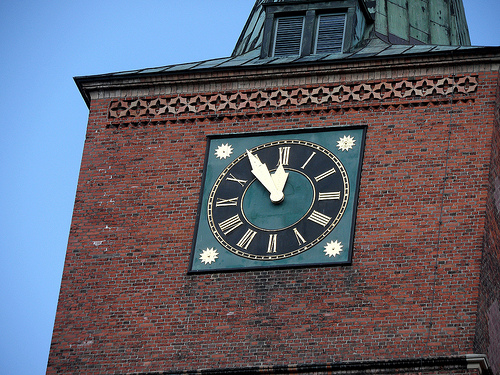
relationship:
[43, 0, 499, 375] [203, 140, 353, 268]
building has clock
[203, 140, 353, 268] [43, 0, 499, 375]
clock on a building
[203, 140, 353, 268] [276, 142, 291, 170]
clock has numeral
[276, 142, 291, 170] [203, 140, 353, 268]
2 on clock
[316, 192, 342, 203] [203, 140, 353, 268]
numeral on clock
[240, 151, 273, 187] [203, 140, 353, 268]
hand on clock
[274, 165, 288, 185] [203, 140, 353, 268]
hand on clock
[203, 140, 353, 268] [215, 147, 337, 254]
clock has face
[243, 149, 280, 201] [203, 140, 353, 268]
hand are on clock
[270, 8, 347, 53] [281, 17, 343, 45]
shutters have slats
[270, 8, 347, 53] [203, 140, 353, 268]
shutters are above clock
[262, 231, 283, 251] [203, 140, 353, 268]
vi on clock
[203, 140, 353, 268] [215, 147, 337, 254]
clock has a face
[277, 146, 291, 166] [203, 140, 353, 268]
numeral on clock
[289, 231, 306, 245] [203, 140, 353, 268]
five on clock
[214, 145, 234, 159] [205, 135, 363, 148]
flower on top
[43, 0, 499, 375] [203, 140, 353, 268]
building has a clock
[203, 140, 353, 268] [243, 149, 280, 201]
clock has hand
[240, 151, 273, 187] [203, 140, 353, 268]
minutes hand on clock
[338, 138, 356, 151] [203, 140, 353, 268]
shape near clock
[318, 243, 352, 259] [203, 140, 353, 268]
shape near clock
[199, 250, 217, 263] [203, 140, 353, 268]
shape near clock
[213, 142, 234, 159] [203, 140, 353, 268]
flower near clock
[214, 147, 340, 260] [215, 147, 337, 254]
numerals are on face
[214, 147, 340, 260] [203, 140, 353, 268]
numerals are on clock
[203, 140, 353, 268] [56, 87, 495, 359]
clock on building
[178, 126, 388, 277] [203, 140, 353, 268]
border on clock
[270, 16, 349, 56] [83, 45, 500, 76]
shutters are on roof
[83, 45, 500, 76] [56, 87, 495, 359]
roof on building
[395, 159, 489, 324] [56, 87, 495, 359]
bricks are on building